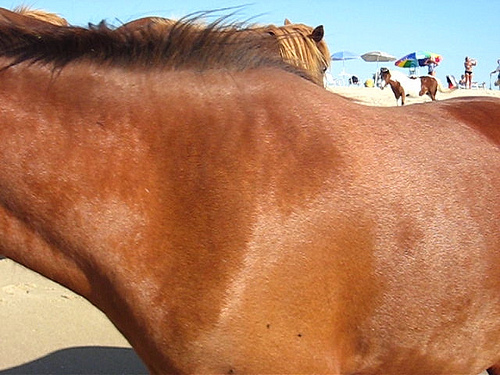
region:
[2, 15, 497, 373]
the big brown horse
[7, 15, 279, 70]
the mane on the brown horse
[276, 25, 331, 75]
the blonde mane on the horse barely visible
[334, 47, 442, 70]
the three beach umbrellas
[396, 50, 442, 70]
the multi colored beach umbrella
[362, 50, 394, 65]
the white beach umbrella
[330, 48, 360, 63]
the blue beach umbrella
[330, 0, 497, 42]
the clear blue sky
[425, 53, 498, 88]
people in the background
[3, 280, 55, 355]
the sand on the ground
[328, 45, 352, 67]
large blue beach umbrella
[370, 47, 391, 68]
large white beach umbrella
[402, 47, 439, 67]
large multi-colored beach umbrella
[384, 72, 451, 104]
white and brown horse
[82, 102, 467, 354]
flank of a brown horse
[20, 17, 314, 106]
dark brown horse mane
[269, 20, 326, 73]
light brown horse mane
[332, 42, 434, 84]
collection of three beach umbrellas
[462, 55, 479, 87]
woman taking a picture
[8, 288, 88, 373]
sandy beach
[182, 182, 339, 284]
A horse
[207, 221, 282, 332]
A horse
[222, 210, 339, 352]
A horse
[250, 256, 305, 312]
A horse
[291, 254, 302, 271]
A horse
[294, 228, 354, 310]
A horse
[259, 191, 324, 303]
A horse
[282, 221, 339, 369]
A horse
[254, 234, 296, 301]
A horse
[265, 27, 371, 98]
Horse in the background.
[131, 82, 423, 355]
Horse with chestnut coloring.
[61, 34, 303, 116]
Man on the horse.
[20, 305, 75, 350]
Sand on the ground.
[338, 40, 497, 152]
umbrellas in the background.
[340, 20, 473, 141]
Brown and white horse.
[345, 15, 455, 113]
Blue sky in the background.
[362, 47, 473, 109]
People by the umbrellas.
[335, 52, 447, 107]
Umbrellas in the sand.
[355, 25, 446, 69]
Rainbow colored umbrella.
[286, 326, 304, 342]
black mark is spotted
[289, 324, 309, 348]
black mark is spotted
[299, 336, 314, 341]
black mark is spotted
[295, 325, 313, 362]
black mark is spotted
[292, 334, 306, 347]
black mark is spotted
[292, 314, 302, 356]
black mark is spotted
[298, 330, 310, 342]
black mark is spotted